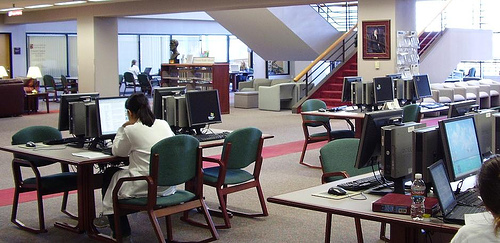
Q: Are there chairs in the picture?
A: Yes, there is a chair.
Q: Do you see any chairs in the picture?
A: Yes, there is a chair.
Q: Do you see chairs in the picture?
A: Yes, there is a chair.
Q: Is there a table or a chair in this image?
A: Yes, there is a chair.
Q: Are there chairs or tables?
A: Yes, there is a chair.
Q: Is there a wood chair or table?
A: Yes, there is a wood chair.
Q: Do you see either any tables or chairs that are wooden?
A: Yes, the chair is wooden.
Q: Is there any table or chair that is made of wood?
A: Yes, the chair is made of wood.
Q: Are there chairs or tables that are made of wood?
A: Yes, the chair is made of wood.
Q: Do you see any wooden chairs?
A: Yes, there is a wood chair.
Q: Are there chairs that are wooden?
A: Yes, there is a chair that is wooden.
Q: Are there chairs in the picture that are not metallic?
A: Yes, there is a wooden chair.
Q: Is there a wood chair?
A: Yes, there is a chair that is made of wood.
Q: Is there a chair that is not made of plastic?
A: Yes, there is a chair that is made of wood.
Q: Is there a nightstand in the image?
A: No, there are no nightstands.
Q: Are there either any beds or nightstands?
A: No, there are no nightstands or beds.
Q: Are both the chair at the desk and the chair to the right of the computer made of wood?
A: Yes, both the chair and the chair are made of wood.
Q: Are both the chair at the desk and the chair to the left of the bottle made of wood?
A: Yes, both the chair and the chair are made of wood.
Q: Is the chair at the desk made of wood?
A: Yes, the chair is made of wood.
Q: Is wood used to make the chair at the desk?
A: Yes, the chair is made of wood.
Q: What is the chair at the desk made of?
A: The chair is made of wood.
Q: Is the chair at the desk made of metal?
A: No, the chair is made of wood.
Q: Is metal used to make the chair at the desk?
A: No, the chair is made of wood.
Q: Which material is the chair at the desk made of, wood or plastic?
A: The chair is made of wood.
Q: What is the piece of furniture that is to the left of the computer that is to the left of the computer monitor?
A: The piece of furniture is a chair.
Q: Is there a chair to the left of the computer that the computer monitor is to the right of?
A: Yes, there is a chair to the left of the computer.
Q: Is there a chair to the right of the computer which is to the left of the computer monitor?
A: No, the chair is to the left of the computer.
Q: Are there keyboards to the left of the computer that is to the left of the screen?
A: No, there is a chair to the left of the computer.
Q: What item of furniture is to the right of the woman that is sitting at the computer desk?
A: The piece of furniture is a chair.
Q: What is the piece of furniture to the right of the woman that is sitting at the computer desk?
A: The piece of furniture is a chair.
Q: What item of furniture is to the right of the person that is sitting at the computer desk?
A: The piece of furniture is a chair.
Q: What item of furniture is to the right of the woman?
A: The piece of furniture is a chair.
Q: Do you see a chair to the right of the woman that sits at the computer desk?
A: Yes, there is a chair to the right of the woman.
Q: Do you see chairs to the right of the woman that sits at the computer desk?
A: Yes, there is a chair to the right of the woman.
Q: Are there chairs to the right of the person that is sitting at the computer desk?
A: Yes, there is a chair to the right of the woman.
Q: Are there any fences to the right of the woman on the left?
A: No, there is a chair to the right of the woman.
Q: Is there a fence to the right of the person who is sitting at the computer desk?
A: No, there is a chair to the right of the woman.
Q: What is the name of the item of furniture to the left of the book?
A: The piece of furniture is a chair.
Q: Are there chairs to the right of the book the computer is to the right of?
A: No, the chair is to the left of the book.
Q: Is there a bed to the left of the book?
A: No, there is a chair to the left of the book.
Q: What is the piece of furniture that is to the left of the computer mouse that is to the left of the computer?
A: The piece of furniture is a chair.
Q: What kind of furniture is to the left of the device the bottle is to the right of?
A: The piece of furniture is a chair.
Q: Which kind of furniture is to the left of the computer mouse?
A: The piece of furniture is a chair.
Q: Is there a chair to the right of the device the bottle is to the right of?
A: No, the chair is to the left of the computer mouse.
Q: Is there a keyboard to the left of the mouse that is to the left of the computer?
A: No, there is a chair to the left of the computer mouse.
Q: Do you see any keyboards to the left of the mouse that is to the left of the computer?
A: No, there is a chair to the left of the computer mouse.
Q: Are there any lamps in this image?
A: Yes, there is a lamp.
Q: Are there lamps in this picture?
A: Yes, there is a lamp.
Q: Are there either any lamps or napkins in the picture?
A: Yes, there is a lamp.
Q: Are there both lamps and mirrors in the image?
A: No, there is a lamp but no mirrors.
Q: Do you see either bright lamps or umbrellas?
A: Yes, there is a bright lamp.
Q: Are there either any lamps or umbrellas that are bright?
A: Yes, the lamp is bright.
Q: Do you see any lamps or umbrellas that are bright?
A: Yes, the lamp is bright.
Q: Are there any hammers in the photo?
A: No, there are no hammers.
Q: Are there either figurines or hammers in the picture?
A: No, there are no hammers or figurines.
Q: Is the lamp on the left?
A: Yes, the lamp is on the left of the image.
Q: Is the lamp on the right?
A: No, the lamp is on the left of the image.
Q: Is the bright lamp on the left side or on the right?
A: The lamp is on the left of the image.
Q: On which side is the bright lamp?
A: The lamp is on the left of the image.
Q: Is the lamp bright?
A: Yes, the lamp is bright.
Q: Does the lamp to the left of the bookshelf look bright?
A: Yes, the lamp is bright.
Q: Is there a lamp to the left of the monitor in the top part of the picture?
A: Yes, there is a lamp to the left of the monitor.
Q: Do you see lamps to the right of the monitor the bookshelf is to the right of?
A: No, the lamp is to the left of the monitor.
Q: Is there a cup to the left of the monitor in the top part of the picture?
A: No, there is a lamp to the left of the monitor.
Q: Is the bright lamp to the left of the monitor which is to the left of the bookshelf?
A: Yes, the lamp is to the left of the monitor.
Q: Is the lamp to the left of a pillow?
A: No, the lamp is to the left of the monitor.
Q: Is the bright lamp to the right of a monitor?
A: No, the lamp is to the left of a monitor.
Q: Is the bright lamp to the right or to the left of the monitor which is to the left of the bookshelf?
A: The lamp is to the left of the monitor.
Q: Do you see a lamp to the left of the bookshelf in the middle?
A: Yes, there is a lamp to the left of the bookshelf.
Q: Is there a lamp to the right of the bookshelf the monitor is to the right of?
A: No, the lamp is to the left of the bookshelf.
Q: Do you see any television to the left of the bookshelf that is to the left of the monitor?
A: No, there is a lamp to the left of the bookshelf.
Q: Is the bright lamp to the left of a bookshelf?
A: Yes, the lamp is to the left of a bookshelf.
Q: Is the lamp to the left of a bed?
A: No, the lamp is to the left of a bookshelf.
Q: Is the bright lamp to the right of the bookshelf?
A: No, the lamp is to the left of the bookshelf.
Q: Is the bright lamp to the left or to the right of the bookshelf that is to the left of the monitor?
A: The lamp is to the left of the bookshelf.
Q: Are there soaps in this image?
A: No, there are no soaps.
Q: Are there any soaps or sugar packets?
A: No, there are no soaps or sugar packets.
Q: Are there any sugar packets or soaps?
A: No, there are no soaps or sugar packets.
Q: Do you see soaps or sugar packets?
A: No, there are no soaps or sugar packets.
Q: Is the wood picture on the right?
A: Yes, the picture is on the right of the image.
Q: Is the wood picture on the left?
A: No, the picture is on the right of the image.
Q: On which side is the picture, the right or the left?
A: The picture is on the right of the image.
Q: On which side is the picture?
A: The picture is on the right of the image.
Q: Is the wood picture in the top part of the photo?
A: Yes, the picture is in the top of the image.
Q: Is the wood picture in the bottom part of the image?
A: No, the picture is in the top of the image.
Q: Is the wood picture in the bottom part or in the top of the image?
A: The picture is in the top of the image.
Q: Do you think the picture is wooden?
A: Yes, the picture is wooden.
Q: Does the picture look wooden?
A: Yes, the picture is wooden.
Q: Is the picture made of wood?
A: Yes, the picture is made of wood.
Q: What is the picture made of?
A: The picture is made of wood.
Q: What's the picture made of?
A: The picture is made of wood.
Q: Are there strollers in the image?
A: No, there are no strollers.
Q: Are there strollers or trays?
A: No, there are no strollers or trays.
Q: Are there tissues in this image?
A: No, there are no tissues.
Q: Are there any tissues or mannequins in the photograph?
A: No, there are no tissues or mannequins.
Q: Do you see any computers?
A: Yes, there is a computer.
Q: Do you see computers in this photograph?
A: Yes, there is a computer.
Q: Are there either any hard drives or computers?
A: Yes, there is a computer.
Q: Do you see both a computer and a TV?
A: No, there is a computer but no televisions.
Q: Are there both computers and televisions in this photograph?
A: No, there is a computer but no televisions.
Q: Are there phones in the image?
A: No, there are no phones.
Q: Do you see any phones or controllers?
A: No, there are no phones or controllers.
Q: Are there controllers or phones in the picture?
A: No, there are no phones or controllers.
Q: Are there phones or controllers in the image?
A: No, there are no phones or controllers.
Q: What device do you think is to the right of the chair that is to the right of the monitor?
A: The device is a computer.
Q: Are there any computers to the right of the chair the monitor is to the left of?
A: Yes, there is a computer to the right of the chair.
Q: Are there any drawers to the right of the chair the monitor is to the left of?
A: No, there is a computer to the right of the chair.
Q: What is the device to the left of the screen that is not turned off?
A: The device is a computer.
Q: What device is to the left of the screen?
A: The device is a computer.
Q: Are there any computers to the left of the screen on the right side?
A: Yes, there is a computer to the left of the screen.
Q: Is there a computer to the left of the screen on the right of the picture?
A: Yes, there is a computer to the left of the screen.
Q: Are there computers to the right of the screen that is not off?
A: No, the computer is to the left of the screen.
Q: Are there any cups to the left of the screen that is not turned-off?
A: No, there is a computer to the left of the screen.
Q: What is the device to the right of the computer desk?
A: The device is a computer.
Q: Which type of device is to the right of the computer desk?
A: The device is a computer.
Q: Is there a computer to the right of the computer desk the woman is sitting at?
A: Yes, there is a computer to the right of the computer desk.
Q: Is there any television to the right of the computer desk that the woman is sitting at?
A: No, there is a computer to the right of the computer desk.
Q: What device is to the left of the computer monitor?
A: The device is a computer.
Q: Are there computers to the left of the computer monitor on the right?
A: Yes, there is a computer to the left of the computer monitor.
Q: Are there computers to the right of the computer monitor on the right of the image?
A: No, the computer is to the left of the computer monitor.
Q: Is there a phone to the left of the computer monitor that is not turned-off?
A: No, there is a computer to the left of the computer monitor.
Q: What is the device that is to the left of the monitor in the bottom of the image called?
A: The device is a computer.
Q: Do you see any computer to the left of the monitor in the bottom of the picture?
A: Yes, there is a computer to the left of the monitor.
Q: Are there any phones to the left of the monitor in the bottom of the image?
A: No, there is a computer to the left of the monitor.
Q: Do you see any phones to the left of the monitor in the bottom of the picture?
A: No, there is a computer to the left of the monitor.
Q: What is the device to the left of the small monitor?
A: The device is a computer.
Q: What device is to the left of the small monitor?
A: The device is a computer.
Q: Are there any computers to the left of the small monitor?
A: Yes, there is a computer to the left of the monitor.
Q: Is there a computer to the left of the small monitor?
A: Yes, there is a computer to the left of the monitor.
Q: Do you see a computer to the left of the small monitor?
A: Yes, there is a computer to the left of the monitor.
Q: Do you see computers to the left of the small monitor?
A: Yes, there is a computer to the left of the monitor.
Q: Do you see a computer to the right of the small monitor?
A: No, the computer is to the left of the monitor.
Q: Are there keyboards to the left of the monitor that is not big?
A: No, there is a computer to the left of the monitor.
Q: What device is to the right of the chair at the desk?
A: The device is a computer.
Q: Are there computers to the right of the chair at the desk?
A: Yes, there is a computer to the right of the chair.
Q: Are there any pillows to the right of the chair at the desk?
A: No, there is a computer to the right of the chair.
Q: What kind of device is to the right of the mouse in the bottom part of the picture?
A: The device is a computer.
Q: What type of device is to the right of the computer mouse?
A: The device is a computer.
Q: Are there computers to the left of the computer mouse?
A: No, the computer is to the right of the computer mouse.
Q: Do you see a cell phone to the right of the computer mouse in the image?
A: No, there is a computer to the right of the computer mouse.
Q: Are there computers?
A: Yes, there is a computer.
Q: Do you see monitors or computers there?
A: Yes, there is a computer.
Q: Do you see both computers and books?
A: Yes, there are both a computer and a book.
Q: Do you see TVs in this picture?
A: No, there are no tvs.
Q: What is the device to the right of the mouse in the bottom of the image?
A: The device is a computer.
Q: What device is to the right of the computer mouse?
A: The device is a computer.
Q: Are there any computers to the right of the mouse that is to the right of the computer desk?
A: Yes, there is a computer to the right of the computer mouse.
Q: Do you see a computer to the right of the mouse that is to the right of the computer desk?
A: Yes, there is a computer to the right of the computer mouse.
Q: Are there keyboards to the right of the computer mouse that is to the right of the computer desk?
A: No, there is a computer to the right of the mouse.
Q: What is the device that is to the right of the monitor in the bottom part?
A: The device is a computer.